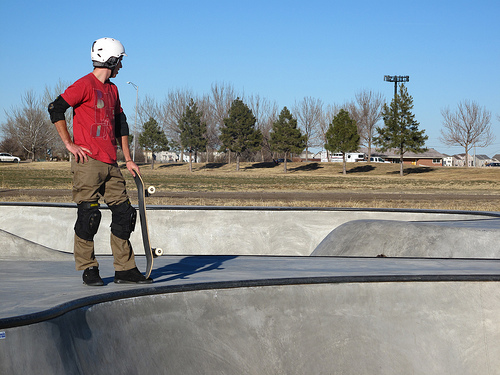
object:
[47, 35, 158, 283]
kid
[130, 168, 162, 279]
skateboard